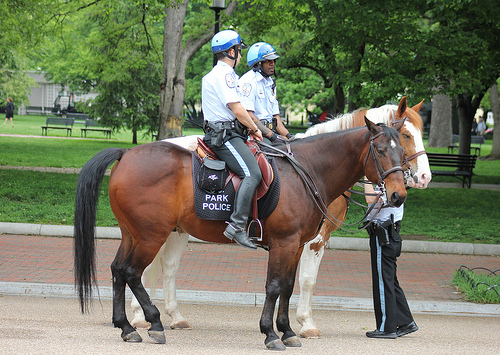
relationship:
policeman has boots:
[197, 24, 274, 253] [223, 176, 259, 250]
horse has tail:
[69, 115, 421, 343] [71, 145, 122, 321]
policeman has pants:
[197, 24, 274, 253] [195, 130, 266, 177]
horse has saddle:
[69, 115, 421, 343] [195, 130, 278, 246]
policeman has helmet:
[197, 24, 274, 253] [208, 28, 245, 55]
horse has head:
[69, 115, 421, 343] [357, 110, 413, 212]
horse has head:
[128, 90, 433, 341] [381, 92, 434, 205]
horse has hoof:
[69, 115, 421, 343] [262, 336, 286, 353]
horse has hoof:
[69, 115, 421, 343] [280, 334, 304, 349]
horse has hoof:
[69, 115, 421, 343] [122, 330, 144, 343]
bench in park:
[40, 112, 76, 138] [4, 0, 499, 254]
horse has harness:
[69, 115, 421, 343] [253, 132, 394, 232]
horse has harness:
[69, 115, 421, 343] [318, 195, 379, 226]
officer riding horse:
[197, 24, 274, 253] [69, 115, 421, 343]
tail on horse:
[71, 145, 122, 321] [69, 115, 421, 343]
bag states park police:
[195, 150, 237, 221] [199, 190, 231, 213]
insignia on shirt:
[223, 72, 237, 91] [199, 59, 243, 121]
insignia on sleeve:
[223, 72, 237, 91] [214, 73, 241, 108]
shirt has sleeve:
[199, 59, 243, 121] [214, 73, 241, 108]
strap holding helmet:
[232, 44, 240, 69] [208, 28, 245, 55]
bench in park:
[80, 116, 115, 140] [4, 0, 499, 254]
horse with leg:
[69, 115, 421, 343] [257, 228, 304, 348]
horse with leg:
[69, 115, 421, 343] [114, 227, 177, 345]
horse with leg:
[128, 90, 433, 341] [293, 236, 328, 350]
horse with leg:
[128, 90, 433, 341] [159, 236, 193, 336]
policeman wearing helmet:
[197, 24, 274, 253] [208, 28, 245, 55]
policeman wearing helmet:
[236, 39, 295, 149] [245, 40, 279, 65]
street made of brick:
[0, 220, 500, 317] [3, 233, 499, 300]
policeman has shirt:
[197, 24, 274, 253] [199, 59, 243, 121]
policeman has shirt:
[236, 39, 295, 149] [238, 74, 288, 127]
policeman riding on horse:
[197, 24, 274, 253] [69, 115, 421, 343]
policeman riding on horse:
[236, 39, 295, 149] [128, 90, 433, 341]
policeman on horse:
[197, 24, 274, 253] [69, 115, 421, 343]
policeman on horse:
[236, 39, 295, 149] [128, 90, 433, 341]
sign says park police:
[189, 149, 245, 223] [199, 190, 231, 213]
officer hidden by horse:
[367, 179, 423, 339] [69, 115, 421, 343]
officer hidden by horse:
[367, 179, 423, 339] [128, 90, 433, 341]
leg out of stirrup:
[219, 135, 264, 249] [246, 220, 266, 242]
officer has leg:
[197, 24, 274, 253] [219, 135, 264, 249]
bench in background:
[40, 112, 76, 138] [4, 0, 500, 248]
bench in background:
[80, 116, 115, 140] [4, 0, 500, 248]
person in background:
[474, 112, 491, 144] [4, 0, 500, 248]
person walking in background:
[474, 112, 491, 144] [4, 0, 500, 248]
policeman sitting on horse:
[197, 24, 274, 253] [69, 115, 421, 343]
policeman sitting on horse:
[236, 39, 295, 149] [128, 90, 433, 341]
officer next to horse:
[367, 179, 423, 339] [69, 115, 421, 343]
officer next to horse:
[367, 179, 423, 339] [128, 90, 433, 341]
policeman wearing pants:
[197, 24, 274, 253] [195, 130, 266, 177]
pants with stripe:
[195, 130, 266, 177] [223, 139, 252, 176]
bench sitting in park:
[40, 112, 76, 138] [4, 0, 499, 254]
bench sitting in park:
[80, 116, 115, 140] [4, 0, 499, 254]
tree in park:
[281, 1, 498, 177] [4, 0, 499, 254]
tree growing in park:
[281, 1, 498, 177] [4, 0, 499, 254]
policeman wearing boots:
[197, 24, 274, 253] [224, 174, 263, 250]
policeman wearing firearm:
[197, 24, 274, 253] [203, 118, 228, 153]